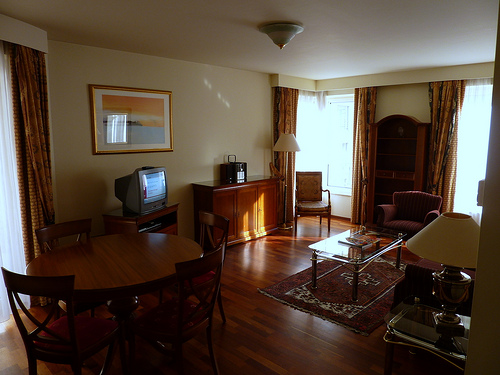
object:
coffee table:
[306, 223, 407, 303]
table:
[24, 230, 205, 374]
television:
[111, 166, 167, 216]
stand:
[100, 203, 181, 236]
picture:
[89, 84, 173, 152]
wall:
[44, 40, 282, 251]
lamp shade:
[271, 133, 300, 153]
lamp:
[403, 212, 482, 325]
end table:
[385, 296, 472, 374]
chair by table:
[123, 252, 224, 375]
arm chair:
[373, 190, 443, 242]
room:
[0, 0, 500, 374]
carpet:
[257, 252, 418, 338]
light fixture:
[256, 21, 304, 49]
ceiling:
[1, 0, 500, 82]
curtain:
[7, 45, 57, 311]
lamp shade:
[405, 212, 480, 268]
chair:
[291, 170, 332, 234]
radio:
[219, 153, 249, 183]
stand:
[190, 174, 279, 248]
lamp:
[275, 133, 295, 230]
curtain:
[271, 87, 298, 228]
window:
[323, 92, 358, 190]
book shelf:
[367, 113, 431, 228]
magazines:
[338, 237, 372, 248]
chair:
[1, 52, 123, 267]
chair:
[198, 212, 231, 324]